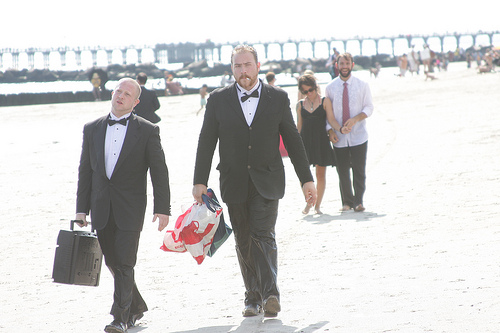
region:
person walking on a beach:
[40, 70, 173, 331]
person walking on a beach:
[152, 35, 318, 329]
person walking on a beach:
[283, 67, 340, 224]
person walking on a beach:
[325, 48, 382, 220]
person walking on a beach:
[133, 70, 164, 126]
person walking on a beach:
[196, 79, 213, 119]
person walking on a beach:
[418, 41, 434, 76]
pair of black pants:
[222, 188, 286, 306]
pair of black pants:
[90, 212, 146, 325]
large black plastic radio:
[46, 211, 109, 296]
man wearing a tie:
[80, 65, 165, 320]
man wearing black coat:
[105, 70, 155, 325]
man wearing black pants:
[85, 70, 160, 325]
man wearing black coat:
[190, 35, 305, 325]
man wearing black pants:
[210, 40, 310, 330]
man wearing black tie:
[210, 45, 310, 330]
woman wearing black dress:
[290, 70, 330, 200]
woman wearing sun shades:
[300, 72, 333, 187]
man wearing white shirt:
[325, 46, 370, 221]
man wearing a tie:
[326, 42, 371, 224]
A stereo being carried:
[52, 219, 104, 284]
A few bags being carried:
[161, 187, 230, 262]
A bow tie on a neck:
[236, 84, 261, 102]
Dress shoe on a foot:
[104, 318, 130, 331]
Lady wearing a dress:
[296, 73, 338, 211]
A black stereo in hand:
[52, 219, 105, 285]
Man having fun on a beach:
[195, 84, 209, 114]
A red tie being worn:
[340, 80, 350, 132]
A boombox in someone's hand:
[55, 219, 105, 284]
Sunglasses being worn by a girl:
[300, 86, 318, 94]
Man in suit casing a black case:
[42, 71, 178, 331]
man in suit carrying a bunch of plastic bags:
[153, 35, 334, 330]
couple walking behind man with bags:
[281, 50, 387, 228]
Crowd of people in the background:
[302, 41, 498, 83]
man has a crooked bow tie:
[223, 71, 277, 111]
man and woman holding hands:
[329, 115, 366, 158]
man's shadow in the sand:
[168, 314, 343, 329]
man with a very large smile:
[319, 48, 369, 83]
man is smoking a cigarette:
[224, 38, 260, 96]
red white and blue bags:
[145, 184, 242, 269]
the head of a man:
[225, 50, 270, 97]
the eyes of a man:
[222, 55, 270, 77]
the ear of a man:
[128, 94, 148, 116]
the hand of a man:
[142, 185, 188, 233]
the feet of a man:
[239, 285, 321, 319]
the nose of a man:
[234, 63, 250, 79]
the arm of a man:
[262, 63, 324, 237]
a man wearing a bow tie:
[226, 74, 308, 120]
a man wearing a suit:
[153, 68, 368, 265]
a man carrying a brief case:
[40, 119, 205, 299]